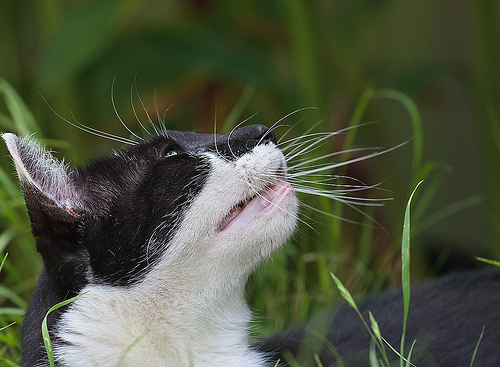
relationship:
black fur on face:
[4, 124, 275, 364] [120, 123, 301, 283]